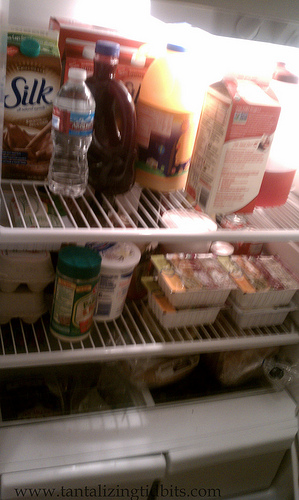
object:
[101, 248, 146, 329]
container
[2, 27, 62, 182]
carton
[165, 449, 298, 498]
carton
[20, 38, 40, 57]
cap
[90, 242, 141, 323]
yogurt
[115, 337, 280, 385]
bread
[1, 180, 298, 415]
shelf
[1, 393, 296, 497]
fridge bottom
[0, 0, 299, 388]
food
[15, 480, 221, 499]
website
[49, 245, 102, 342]
container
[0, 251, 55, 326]
eggs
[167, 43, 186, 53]
cap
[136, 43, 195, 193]
bottle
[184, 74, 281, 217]
carton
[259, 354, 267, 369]
tie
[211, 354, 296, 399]
plastic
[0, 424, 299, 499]
drawers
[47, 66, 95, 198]
bottle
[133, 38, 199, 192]
juice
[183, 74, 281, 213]
milk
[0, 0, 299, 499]
fridge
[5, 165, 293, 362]
bar